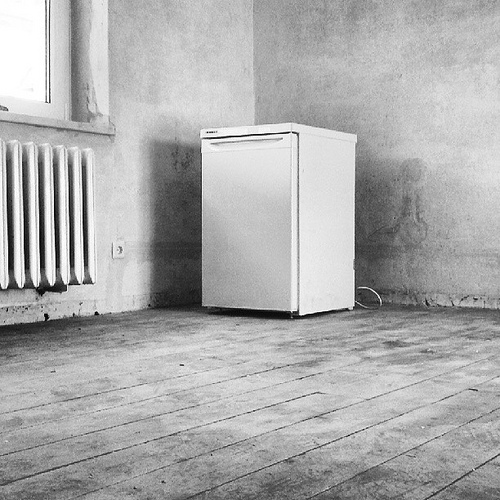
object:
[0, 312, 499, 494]
floor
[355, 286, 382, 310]
wire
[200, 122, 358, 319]
fridge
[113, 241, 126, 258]
outlet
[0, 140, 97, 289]
radiator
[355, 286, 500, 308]
paint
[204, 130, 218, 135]
brand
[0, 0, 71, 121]
window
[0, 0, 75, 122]
frame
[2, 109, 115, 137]
sill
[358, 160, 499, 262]
wall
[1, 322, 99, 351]
dirt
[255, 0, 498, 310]
wall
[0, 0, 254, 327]
wall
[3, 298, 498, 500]
more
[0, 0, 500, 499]
picture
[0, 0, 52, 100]
light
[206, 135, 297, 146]
handle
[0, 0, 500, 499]
room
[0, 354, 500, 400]
line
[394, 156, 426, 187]
spot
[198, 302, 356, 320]
shadow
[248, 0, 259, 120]
edge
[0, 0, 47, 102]
glass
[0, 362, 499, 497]
wood